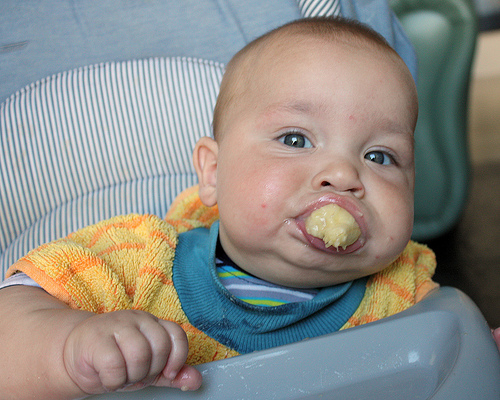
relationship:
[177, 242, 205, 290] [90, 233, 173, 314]
collar of shirt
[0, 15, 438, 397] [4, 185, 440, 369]
baby has bib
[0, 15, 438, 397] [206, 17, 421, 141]
baby has hair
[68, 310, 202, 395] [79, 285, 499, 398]
clenched fist on object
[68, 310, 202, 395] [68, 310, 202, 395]
clenched fist clenched into a clenched fist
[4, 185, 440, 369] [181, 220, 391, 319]
bib around neck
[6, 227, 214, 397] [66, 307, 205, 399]
arm with clenched fist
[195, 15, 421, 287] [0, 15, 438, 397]
head of baby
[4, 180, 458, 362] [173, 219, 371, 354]
bib with collar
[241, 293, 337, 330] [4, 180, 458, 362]
shirt under bib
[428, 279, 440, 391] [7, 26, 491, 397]
tray of high chair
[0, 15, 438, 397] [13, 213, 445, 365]
baby wearing bib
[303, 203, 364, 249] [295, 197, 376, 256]
food in baby's mouth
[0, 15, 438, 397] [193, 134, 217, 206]
baby has ear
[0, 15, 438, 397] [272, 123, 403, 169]
baby has eyes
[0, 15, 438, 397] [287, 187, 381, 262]
baby spitting out food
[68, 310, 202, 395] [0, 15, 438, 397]
clenched fist on baby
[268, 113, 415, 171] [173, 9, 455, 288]
eyes on baby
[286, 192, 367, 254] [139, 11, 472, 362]
baby's mouth on baby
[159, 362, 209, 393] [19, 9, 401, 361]
thumb on baby